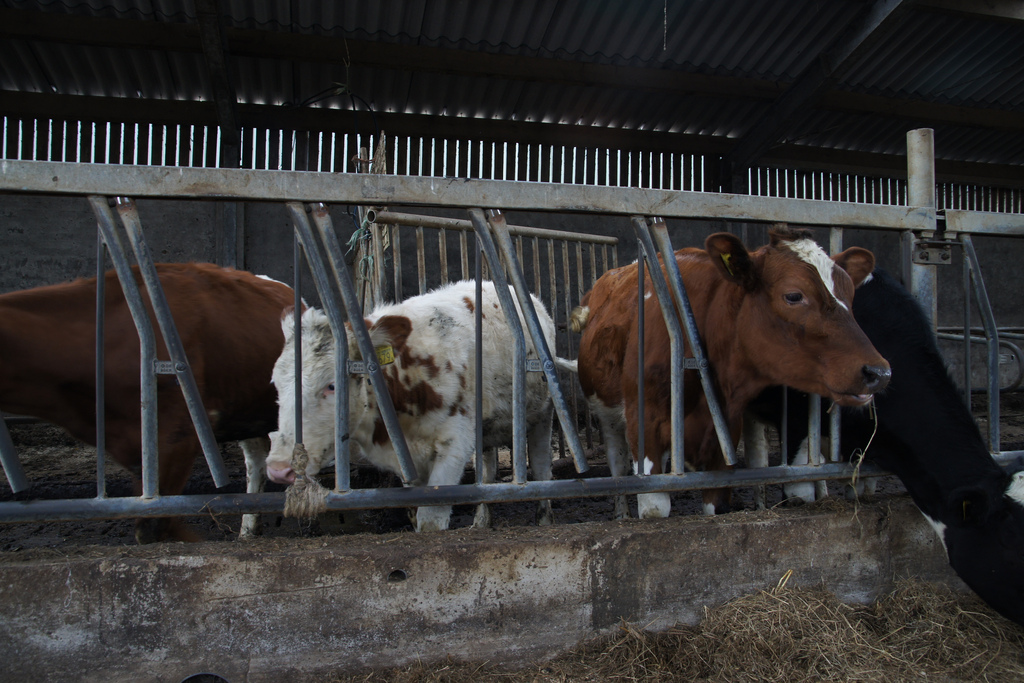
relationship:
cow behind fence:
[6, 250, 281, 480] [6, 146, 1022, 533]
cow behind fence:
[557, 224, 903, 488] [6, 146, 1022, 533]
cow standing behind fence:
[834, 256, 992, 606] [13, 135, 990, 496]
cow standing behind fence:
[561, 230, 899, 509] [13, 135, 990, 496]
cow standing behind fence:
[268, 286, 567, 528] [13, 135, 990, 496]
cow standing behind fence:
[8, 238, 311, 524] [13, 135, 990, 496]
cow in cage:
[840, 273, 992, 585] [21, 122, 992, 593]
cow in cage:
[574, 234, 907, 490] [21, 122, 992, 593]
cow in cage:
[255, 264, 569, 558] [21, 122, 992, 593]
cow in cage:
[8, 238, 311, 524] [21, 122, 992, 593]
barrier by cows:
[26, 487, 962, 641] [10, 227, 991, 534]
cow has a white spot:
[561, 230, 899, 509] [765, 215, 854, 304]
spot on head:
[765, 215, 854, 304] [693, 201, 892, 409]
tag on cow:
[373, 335, 399, 370] [262, 273, 580, 533]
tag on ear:
[373, 335, 399, 370] [361, 305, 420, 357]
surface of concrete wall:
[11, 549, 785, 632] [19, 497, 946, 645]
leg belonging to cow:
[528, 404, 555, 528] [262, 273, 580, 533]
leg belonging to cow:
[465, 431, 502, 525] [262, 273, 580, 533]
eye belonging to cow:
[322, 379, 340, 395] [262, 273, 580, 533]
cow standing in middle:
[262, 273, 580, 533] [238, 128, 617, 539]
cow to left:
[4, 262, 324, 533] [2, 7, 240, 679]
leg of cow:
[425, 426, 467, 567] [265, 268, 601, 545]